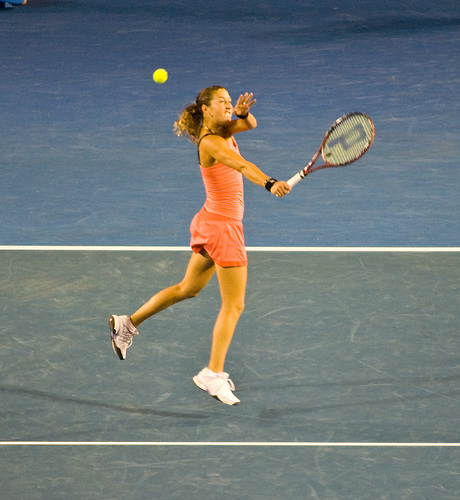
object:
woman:
[107, 84, 378, 410]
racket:
[271, 111, 375, 201]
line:
[0, 245, 458, 255]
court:
[0, 0, 460, 500]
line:
[0, 436, 458, 449]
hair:
[172, 84, 222, 144]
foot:
[189, 362, 245, 406]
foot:
[106, 313, 142, 364]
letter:
[326, 123, 367, 154]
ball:
[151, 67, 171, 86]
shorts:
[188, 203, 250, 269]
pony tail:
[174, 99, 205, 141]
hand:
[267, 179, 291, 200]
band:
[263, 176, 276, 193]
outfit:
[188, 136, 250, 269]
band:
[235, 114, 251, 119]